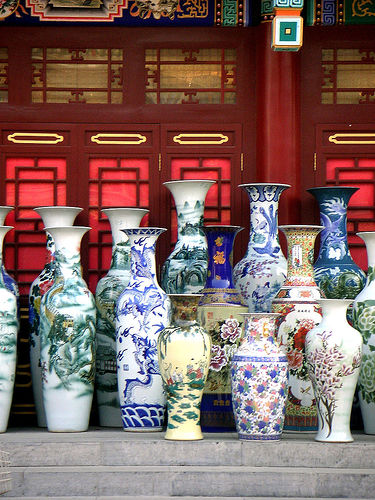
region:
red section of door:
[5, 156, 31, 179]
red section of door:
[37, 158, 65, 181]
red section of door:
[17, 166, 53, 177]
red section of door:
[5, 179, 16, 205]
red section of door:
[16, 179, 51, 208]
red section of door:
[55, 183, 65, 204]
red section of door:
[89, 157, 116, 178]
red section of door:
[120, 156, 146, 180]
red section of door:
[102, 168, 136, 181]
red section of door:
[202, 157, 228, 177]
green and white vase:
[39, 224, 101, 430]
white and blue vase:
[115, 227, 168, 430]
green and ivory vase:
[158, 294, 207, 440]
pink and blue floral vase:
[231, 311, 291, 436]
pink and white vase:
[305, 298, 362, 442]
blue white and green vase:
[307, 185, 365, 298]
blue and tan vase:
[197, 223, 245, 430]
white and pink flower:
[220, 318, 241, 342]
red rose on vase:
[292, 327, 307, 347]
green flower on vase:
[356, 304, 374, 335]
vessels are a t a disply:
[5, 205, 369, 494]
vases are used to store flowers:
[54, 230, 362, 430]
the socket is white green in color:
[274, 17, 316, 55]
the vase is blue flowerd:
[115, 235, 157, 462]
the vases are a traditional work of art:
[31, 209, 357, 449]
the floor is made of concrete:
[133, 446, 225, 498]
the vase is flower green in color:
[162, 312, 219, 444]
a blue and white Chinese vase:
[108, 220, 179, 435]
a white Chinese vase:
[301, 292, 366, 451]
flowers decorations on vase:
[301, 329, 361, 441]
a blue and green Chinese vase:
[308, 179, 366, 296]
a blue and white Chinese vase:
[36, 221, 103, 436]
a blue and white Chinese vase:
[154, 168, 215, 289]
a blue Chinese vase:
[198, 221, 247, 293]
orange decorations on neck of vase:
[210, 236, 230, 268]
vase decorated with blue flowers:
[228, 305, 291, 443]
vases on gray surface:
[6, 172, 373, 498]